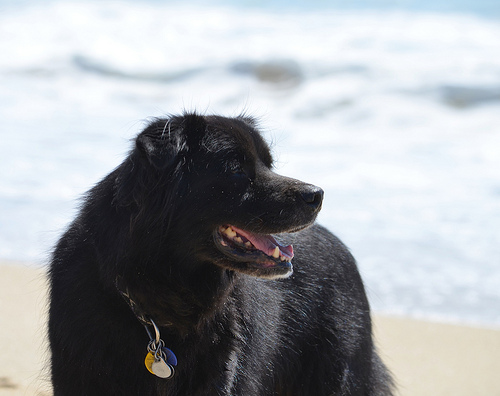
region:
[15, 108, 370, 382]
big black dog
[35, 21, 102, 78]
white and blue ocean waves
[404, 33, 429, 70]
white and blue ocean waves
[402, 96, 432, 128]
white and blue ocean waves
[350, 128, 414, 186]
white and blue ocean waves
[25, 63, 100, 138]
white and blue ocean waves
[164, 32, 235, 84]
white and blue ocean waves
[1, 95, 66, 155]
white and blue ocean waves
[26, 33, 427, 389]
a dog on the shore of a beach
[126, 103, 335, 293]
the head of a dog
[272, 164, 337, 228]
the nose of a dog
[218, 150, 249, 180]
the eye of a dog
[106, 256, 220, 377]
the collar of a dog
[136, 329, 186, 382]
the tags of a dog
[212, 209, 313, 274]
the mouth of a dog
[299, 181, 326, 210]
the nose of a dog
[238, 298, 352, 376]
the fur of a dog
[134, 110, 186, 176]
the ear of a dog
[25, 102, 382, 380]
black dog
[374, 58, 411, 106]
white and green ocean waves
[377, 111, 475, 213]
white and green ocean waves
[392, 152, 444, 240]
white and green ocean waves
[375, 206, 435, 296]
white and green ocean waves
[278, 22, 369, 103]
white and green ocean waves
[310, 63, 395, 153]
white and green ocean waves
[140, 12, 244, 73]
white and green ocean waves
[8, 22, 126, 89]
white and green ocean waves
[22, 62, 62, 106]
white and green ocean waves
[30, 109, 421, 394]
large black dog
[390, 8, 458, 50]
white clouds in blue sky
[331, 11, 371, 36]
white clouds in blue sky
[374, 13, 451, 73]
white clouds in blue sky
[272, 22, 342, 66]
white clouds in blue sky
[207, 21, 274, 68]
white clouds in blue sky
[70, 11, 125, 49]
white clouds in blue sky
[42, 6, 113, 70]
white clouds in blue sky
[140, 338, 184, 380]
charms on the chain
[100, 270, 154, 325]
collar on the dog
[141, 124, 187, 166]
black ear on dog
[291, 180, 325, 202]
black nose on dog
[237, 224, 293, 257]
the tongue onf the dog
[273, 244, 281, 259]
the dog's sharp tooth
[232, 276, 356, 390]
black fur on the dog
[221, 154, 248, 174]
right eye on dog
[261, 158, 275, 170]
left eye on the dog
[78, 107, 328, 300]
head of the dog